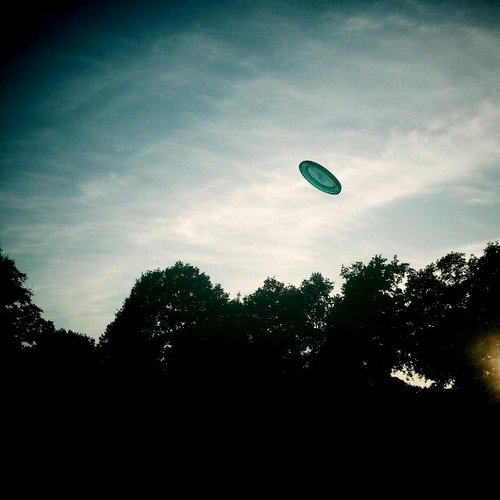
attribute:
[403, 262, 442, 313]
leaf — dark 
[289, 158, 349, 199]
frisbee — mid flight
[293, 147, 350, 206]
frisbee — blue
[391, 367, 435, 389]
break — small 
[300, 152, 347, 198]
frisbee — oval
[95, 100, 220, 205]
clouds — white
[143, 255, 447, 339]
trees — dark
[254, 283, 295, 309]
leaves — green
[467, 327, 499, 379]
glimmer — shining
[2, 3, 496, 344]
sky — dark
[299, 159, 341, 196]
frisbee — green , flying, circle, mid air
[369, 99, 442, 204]
clouds — white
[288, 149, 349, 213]
frisbee — tilted 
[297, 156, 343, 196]
circle — black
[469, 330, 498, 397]
sun — shining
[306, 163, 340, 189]
circle — round, inner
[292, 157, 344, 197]
frisbee — blue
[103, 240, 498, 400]
trees — deciduous 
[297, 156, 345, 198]
frisbee — round, green, flying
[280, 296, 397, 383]
trees — green 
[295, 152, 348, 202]
frisbee — mid air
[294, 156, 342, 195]
shape — circular